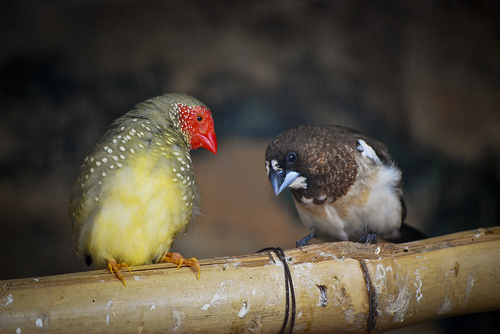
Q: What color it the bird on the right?
A: Yellow.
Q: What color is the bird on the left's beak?
A: Red.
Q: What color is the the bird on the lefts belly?
A: White.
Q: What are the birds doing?
A: Standing.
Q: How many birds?
A: Two.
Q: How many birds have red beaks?
A: One.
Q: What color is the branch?
A: Tan.